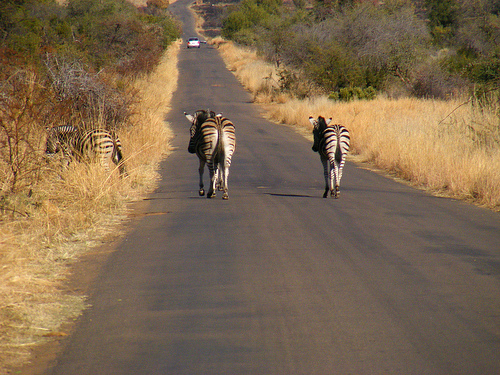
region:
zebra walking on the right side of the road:
[303, 113, 352, 203]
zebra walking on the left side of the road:
[183, 104, 238, 201]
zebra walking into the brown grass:
[37, 119, 129, 194]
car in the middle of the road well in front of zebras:
[185, 34, 200, 52]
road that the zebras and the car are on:
[43, 2, 498, 373]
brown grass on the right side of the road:
[203, 19, 498, 206]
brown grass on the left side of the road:
[0, 38, 179, 373]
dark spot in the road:
[152, 205, 236, 365]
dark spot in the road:
[415, 224, 497, 281]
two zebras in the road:
[169, 87, 361, 218]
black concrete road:
[174, 228, 388, 360]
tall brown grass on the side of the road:
[383, 111, 436, 174]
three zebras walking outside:
[42, 101, 356, 206]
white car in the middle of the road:
[181, 14, 206, 51]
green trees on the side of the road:
[312, 21, 458, 100]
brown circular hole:
[134, 208, 169, 223]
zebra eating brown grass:
[38, 111, 130, 188]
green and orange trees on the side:
[14, 8, 131, 78]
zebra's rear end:
[204, 114, 234, 159]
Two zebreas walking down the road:
[182, 104, 357, 201]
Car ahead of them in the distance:
[184, 32, 205, 53]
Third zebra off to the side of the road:
[39, 119, 132, 177]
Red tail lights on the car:
[183, 35, 208, 50]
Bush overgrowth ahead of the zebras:
[278, 21, 495, 102]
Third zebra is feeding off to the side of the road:
[40, 114, 141, 181]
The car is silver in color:
[183, 26, 205, 55]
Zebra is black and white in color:
[309, 118, 360, 203]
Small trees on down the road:
[222, 7, 464, 89]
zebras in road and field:
[39, 100, 362, 196]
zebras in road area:
[181, 85, 358, 202]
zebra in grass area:
[30, 108, 134, 184]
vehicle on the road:
[183, 30, 205, 55]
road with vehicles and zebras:
[171, 4, 389, 367]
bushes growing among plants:
[327, 73, 380, 103]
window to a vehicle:
[184, 37, 200, 41]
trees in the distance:
[221, 9, 269, 31]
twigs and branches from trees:
[451, 88, 493, 119]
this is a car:
[183, 15, 223, 68]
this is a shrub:
[4, 60, 56, 220]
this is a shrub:
[282, 30, 394, 117]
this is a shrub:
[72, 15, 179, 107]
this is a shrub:
[435, 21, 494, 135]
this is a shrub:
[29, 8, 101, 81]